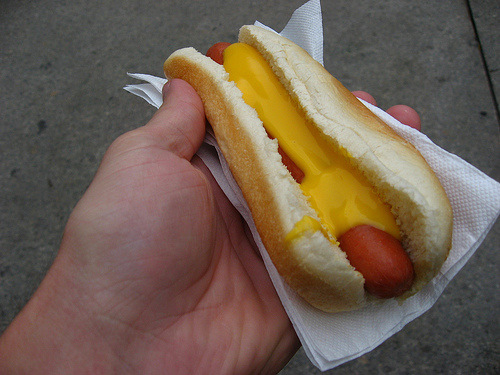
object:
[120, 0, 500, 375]
napkin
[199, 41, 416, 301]
hot dog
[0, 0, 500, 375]
gray cement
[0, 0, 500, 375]
counter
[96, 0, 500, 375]
hand holding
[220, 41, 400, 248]
cheese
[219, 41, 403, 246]
mustard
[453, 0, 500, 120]
streak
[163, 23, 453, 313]
bun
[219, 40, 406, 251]
sauce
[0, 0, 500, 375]
gray sidewalk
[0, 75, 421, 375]
hand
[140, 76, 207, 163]
thumb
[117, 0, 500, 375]
doh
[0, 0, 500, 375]
pavement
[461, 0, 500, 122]
line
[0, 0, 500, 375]
ground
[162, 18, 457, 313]
weiner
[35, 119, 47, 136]
spot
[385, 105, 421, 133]
finger